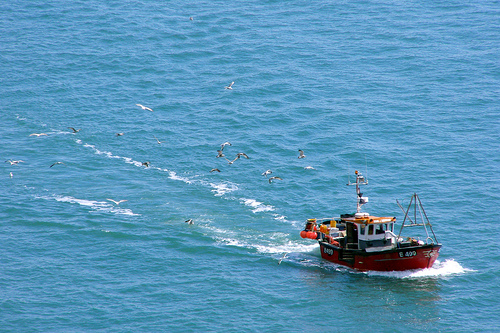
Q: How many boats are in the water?
A: One.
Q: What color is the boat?
A: Red.